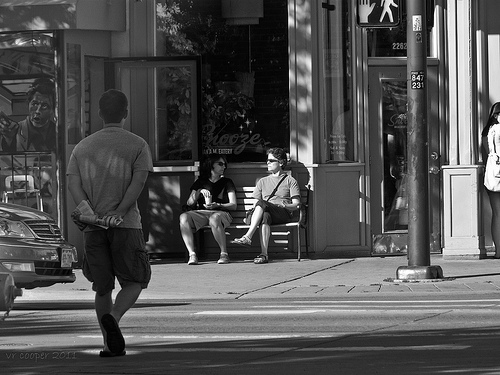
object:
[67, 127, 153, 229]
shirt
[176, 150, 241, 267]
woman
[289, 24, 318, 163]
sunlight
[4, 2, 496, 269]
building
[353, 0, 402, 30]
sign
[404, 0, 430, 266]
pole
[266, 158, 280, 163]
sunglasses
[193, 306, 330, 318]
white line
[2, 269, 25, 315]
cover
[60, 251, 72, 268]
car tag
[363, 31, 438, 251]
door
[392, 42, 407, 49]
address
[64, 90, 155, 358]
man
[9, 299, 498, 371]
street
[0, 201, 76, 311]
car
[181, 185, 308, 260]
bench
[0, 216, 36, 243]
lamp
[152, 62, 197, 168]
window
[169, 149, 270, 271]
woman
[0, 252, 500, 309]
sidewalk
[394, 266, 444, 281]
post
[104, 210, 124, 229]
hand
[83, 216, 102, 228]
hand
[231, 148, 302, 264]
woman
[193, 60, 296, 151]
window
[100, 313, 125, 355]
shoe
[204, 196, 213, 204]
beverage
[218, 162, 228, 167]
sunglasses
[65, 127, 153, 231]
back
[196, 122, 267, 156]
name